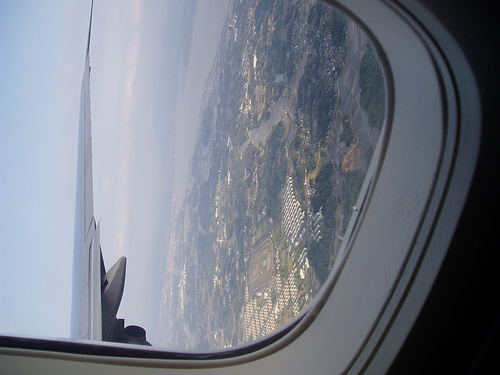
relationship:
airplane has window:
[0, 0, 499, 375] [0, 1, 486, 374]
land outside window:
[154, 2, 385, 357] [0, 1, 486, 374]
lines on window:
[339, 0, 472, 375] [0, 1, 486, 374]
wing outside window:
[70, 2, 104, 347] [0, 1, 486, 374]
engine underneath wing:
[100, 253, 154, 345] [70, 2, 104, 347]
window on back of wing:
[0, 1, 486, 374] [70, 2, 104, 347]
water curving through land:
[233, 81, 303, 171] [154, 2, 385, 357]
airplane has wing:
[0, 0, 499, 375] [70, 2, 104, 347]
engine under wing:
[100, 253, 154, 345] [70, 2, 104, 347]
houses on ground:
[303, 207, 325, 247] [154, 2, 385, 357]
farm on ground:
[242, 234, 278, 292] [154, 2, 385, 357]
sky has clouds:
[1, 1, 228, 346] [116, 7, 193, 311]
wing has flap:
[70, 2, 104, 347] [88, 223, 111, 341]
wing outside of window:
[70, 2, 104, 347] [0, 1, 486, 374]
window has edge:
[0, 1, 486, 374] [322, 56, 478, 374]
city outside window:
[154, 2, 385, 357] [0, 1, 486, 374]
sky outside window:
[1, 1, 228, 346] [0, 1, 486, 374]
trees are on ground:
[257, 119, 286, 223] [154, 2, 385, 357]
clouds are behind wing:
[116, 7, 193, 311] [70, 2, 104, 347]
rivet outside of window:
[349, 204, 359, 212] [0, 1, 486, 374]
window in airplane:
[0, 1, 486, 374] [0, 0, 499, 375]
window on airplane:
[0, 1, 486, 374] [0, 0, 499, 375]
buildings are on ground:
[280, 177, 309, 250] [154, 2, 385, 357]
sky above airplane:
[1, 1, 228, 346] [0, 0, 499, 375]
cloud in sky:
[114, 3, 143, 266] [1, 1, 228, 346]